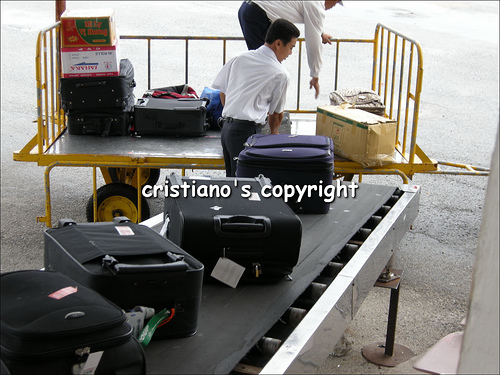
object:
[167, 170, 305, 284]
luggage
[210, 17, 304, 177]
man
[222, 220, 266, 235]
handle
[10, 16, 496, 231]
cart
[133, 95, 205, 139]
luggage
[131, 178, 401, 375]
conveyor belt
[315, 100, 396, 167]
box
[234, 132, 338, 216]
suitcase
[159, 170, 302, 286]
suitcase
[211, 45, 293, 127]
shirt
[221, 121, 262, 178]
pants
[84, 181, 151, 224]
wheels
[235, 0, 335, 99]
man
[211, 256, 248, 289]
name tag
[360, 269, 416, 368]
steel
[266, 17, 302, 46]
hair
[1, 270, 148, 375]
luggage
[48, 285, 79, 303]
tag